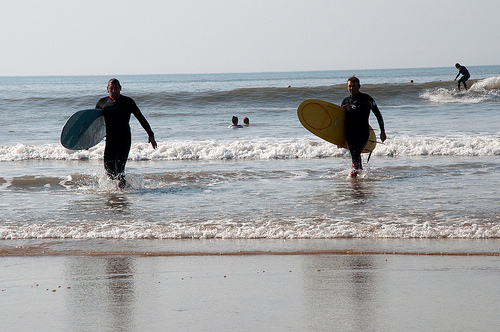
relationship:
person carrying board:
[95, 78, 158, 189] [56, 107, 106, 151]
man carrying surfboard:
[338, 74, 387, 179] [298, 99, 375, 152]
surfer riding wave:
[453, 63, 470, 90] [351, 70, 486, 135]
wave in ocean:
[210, 131, 292, 166] [164, 70, 296, 96]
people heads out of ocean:
[227, 115, 244, 128] [0, 66, 499, 238]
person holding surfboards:
[95, 78, 158, 189] [297, 103, 380, 152]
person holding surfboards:
[95, 78, 158, 189] [56, 106, 105, 148]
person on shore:
[95, 78, 158, 189] [16, 49, 477, 256]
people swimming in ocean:
[227, 106, 253, 131] [10, 72, 498, 221]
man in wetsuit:
[306, 81, 388, 158] [339, 80, 404, 127]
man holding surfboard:
[306, 81, 388, 158] [281, 96, 376, 156]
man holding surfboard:
[338, 74, 387, 179] [290, 89, 343, 141]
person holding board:
[97, 81, 137, 191] [60, 109, 107, 150]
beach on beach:
[0, 237, 500, 332] [3, 232, 498, 325]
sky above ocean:
[248, 2, 415, 81] [3, 2, 498, 79]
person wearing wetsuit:
[95, 78, 158, 189] [89, 96, 152, 186]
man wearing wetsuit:
[338, 74, 387, 179] [339, 92, 389, 169]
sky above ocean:
[0, 2, 500, 82] [2, 71, 499, 246]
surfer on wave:
[447, 60, 474, 95] [8, 69, 498, 118]